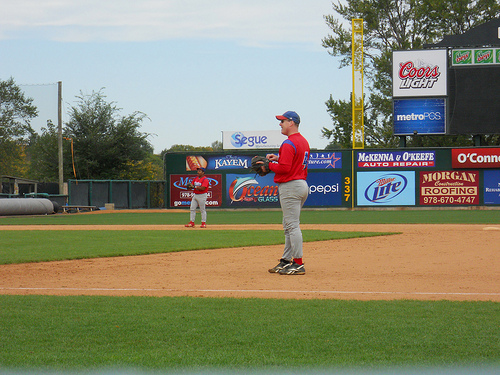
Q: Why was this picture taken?
A: To show the baseball game.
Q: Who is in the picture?
A: Two players are in the picture.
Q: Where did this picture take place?
A: It took place on the baseball field.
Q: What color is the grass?
A: The grass is green.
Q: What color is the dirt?
A: The dirt is brown.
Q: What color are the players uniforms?
A: The uniforms are red and grey.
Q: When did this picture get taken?
A: It was taken in the day time.